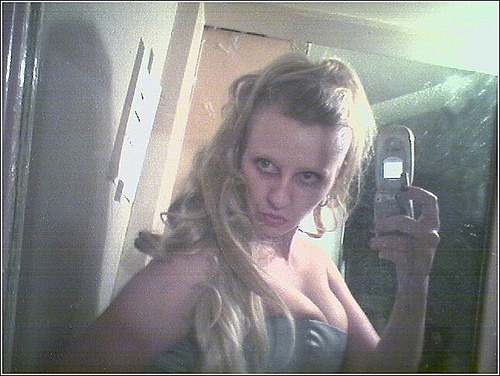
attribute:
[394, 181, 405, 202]
polish — red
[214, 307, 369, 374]
top — gray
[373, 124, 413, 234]
cell phone — gray, on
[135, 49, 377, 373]
hair — blonde,  loosely curled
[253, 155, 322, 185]
eyes — blue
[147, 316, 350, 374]
dress — low cut 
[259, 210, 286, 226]
lipstick — red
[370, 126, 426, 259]
phone — small, flip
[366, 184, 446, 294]
hand — woman's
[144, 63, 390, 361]
woman — blond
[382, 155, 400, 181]
screen — lcd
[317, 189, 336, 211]
earring — golden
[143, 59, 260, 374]
hair — blond